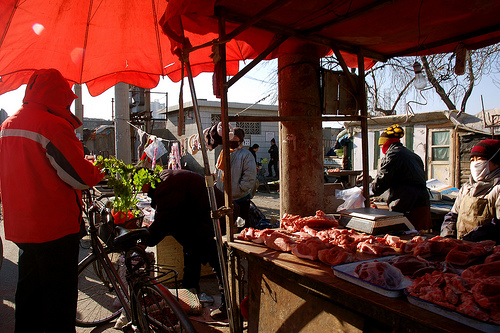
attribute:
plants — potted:
[91, 151, 165, 227]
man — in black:
[136, 166, 307, 301]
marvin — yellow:
[377, 123, 404, 146]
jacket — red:
[0, 66, 100, 241]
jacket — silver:
[214, 148, 257, 198]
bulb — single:
[30, 19, 43, 39]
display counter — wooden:
[228, 227, 498, 331]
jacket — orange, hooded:
[0, 55, 103, 247]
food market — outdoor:
[50, 86, 385, 283]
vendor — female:
[367, 113, 420, 213]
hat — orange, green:
[380, 123, 398, 146]